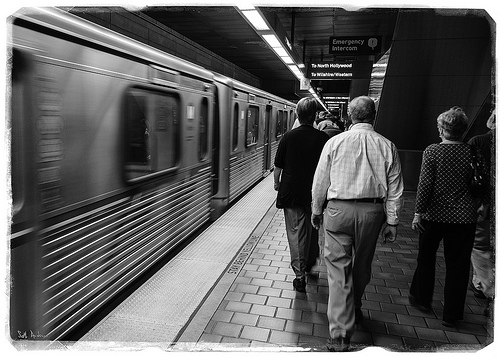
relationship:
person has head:
[271, 94, 333, 297] [291, 96, 320, 126]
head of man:
[346, 95, 378, 125] [309, 96, 399, 352]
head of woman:
[435, 106, 469, 143] [409, 107, 479, 329]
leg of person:
[283, 207, 309, 277] [271, 94, 333, 297]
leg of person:
[306, 208, 322, 274] [271, 94, 333, 297]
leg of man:
[324, 231, 354, 339] [309, 96, 399, 352]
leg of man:
[355, 234, 376, 320] [309, 96, 399, 352]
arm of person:
[272, 132, 288, 191] [271, 94, 333, 297]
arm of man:
[312, 139, 333, 215] [309, 96, 399, 352]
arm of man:
[387, 139, 404, 225] [309, 96, 399, 352]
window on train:
[119, 82, 183, 183] [10, 8, 296, 341]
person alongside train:
[271, 94, 333, 297] [10, 8, 296, 341]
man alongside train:
[309, 96, 399, 352] [10, 8, 296, 341]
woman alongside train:
[409, 107, 479, 329] [10, 8, 296, 341]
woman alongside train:
[467, 108, 496, 299] [10, 8, 296, 341]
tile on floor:
[254, 313, 290, 332] [75, 168, 490, 347]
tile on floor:
[251, 256, 273, 268] [75, 168, 490, 347]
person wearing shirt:
[271, 94, 333, 297] [274, 125, 328, 207]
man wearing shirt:
[309, 96, 399, 352] [311, 124, 404, 225]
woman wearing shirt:
[409, 107, 479, 329] [412, 140, 479, 221]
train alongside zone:
[10, 8, 296, 341] [76, 167, 277, 345]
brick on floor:
[396, 310, 427, 328] [75, 168, 490, 347]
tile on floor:
[211, 320, 244, 339] [75, 168, 490, 347]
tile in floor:
[414, 322, 448, 344] [75, 168, 490, 347]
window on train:
[196, 95, 211, 163] [10, 8, 296, 341]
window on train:
[232, 100, 241, 151] [10, 8, 296, 341]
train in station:
[10, 8, 296, 341] [10, 10, 487, 348]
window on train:
[244, 103, 261, 147] [10, 8, 296, 341]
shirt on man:
[311, 124, 404, 225] [309, 96, 399, 352]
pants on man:
[322, 203, 385, 338] [309, 96, 399, 352]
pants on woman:
[408, 220, 476, 322] [409, 107, 479, 329]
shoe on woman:
[408, 294, 432, 312] [409, 107, 479, 329]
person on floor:
[271, 94, 333, 297] [198, 208, 490, 348]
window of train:
[119, 82, 183, 183] [10, 8, 296, 341]